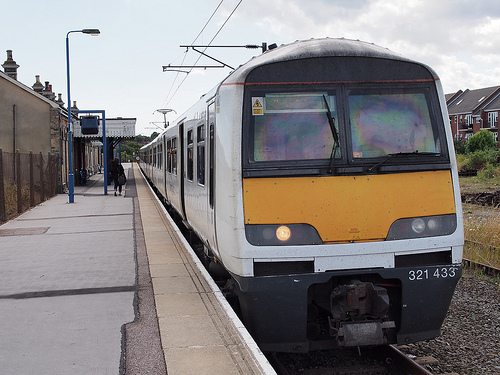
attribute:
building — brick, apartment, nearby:
[447, 88, 485, 140]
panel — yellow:
[243, 168, 458, 246]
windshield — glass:
[243, 83, 452, 177]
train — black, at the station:
[138, 37, 468, 351]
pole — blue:
[66, 31, 82, 202]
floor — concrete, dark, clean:
[0, 162, 279, 374]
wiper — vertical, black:
[323, 93, 340, 173]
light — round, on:
[277, 226, 293, 241]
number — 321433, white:
[405, 265, 458, 281]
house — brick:
[447, 85, 499, 150]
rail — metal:
[375, 338, 432, 374]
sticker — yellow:
[250, 96, 266, 120]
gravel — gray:
[469, 328, 477, 336]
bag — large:
[116, 172, 127, 187]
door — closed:
[206, 100, 220, 262]